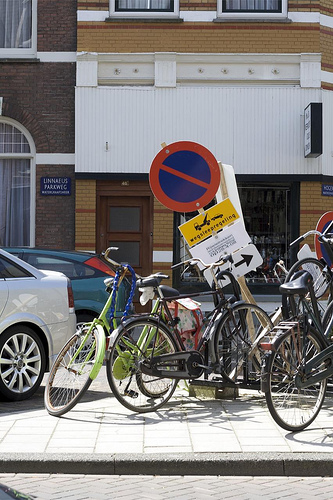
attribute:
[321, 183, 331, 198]
sign — is small, is blue, is white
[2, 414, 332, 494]
pavement — is red, is small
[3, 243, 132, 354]
car — green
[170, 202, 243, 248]
sign — is small, is black, is yellow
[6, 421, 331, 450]
street — made of cement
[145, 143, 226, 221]
sign — no parking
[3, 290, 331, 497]
street — is brown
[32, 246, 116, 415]
color bike — green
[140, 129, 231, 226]
sign — is red, is blue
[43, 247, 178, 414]
bike — four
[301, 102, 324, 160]
electrical sign — is black, is white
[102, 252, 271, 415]
bike — black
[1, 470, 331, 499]
brick pavement — is small, is red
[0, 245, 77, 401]
car — white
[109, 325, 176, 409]
wheel — back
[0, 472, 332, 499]
road — brick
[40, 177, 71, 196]
sign — is blue, is white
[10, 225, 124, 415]
car — is teal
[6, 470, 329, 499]
pavement — is small, is red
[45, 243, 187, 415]
bicycle — blue, green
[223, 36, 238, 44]
brick — is small, is red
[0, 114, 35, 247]
window — arched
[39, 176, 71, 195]
sign — is small, is blue, is white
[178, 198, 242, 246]
sign — is black, is yellow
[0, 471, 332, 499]
red brick — is red, is small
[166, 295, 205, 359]
box — is multi-colored